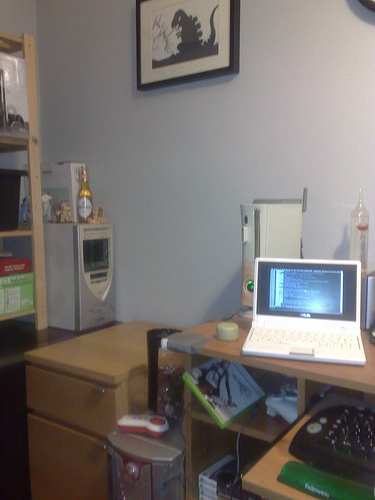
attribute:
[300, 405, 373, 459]
keyboard — black, computer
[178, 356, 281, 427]
dvd — stack, case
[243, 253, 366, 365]
laptop — white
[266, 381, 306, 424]
controller — video game